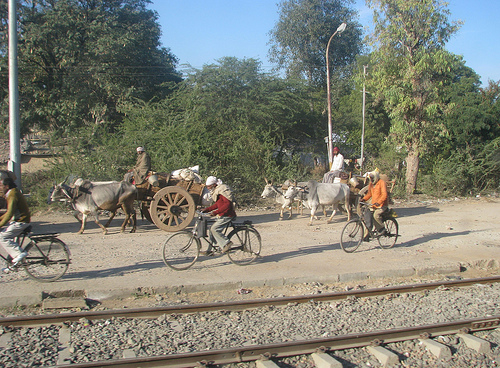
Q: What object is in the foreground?
A: Train tracks.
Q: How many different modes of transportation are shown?
A: Two.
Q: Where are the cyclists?
A: Between the train tracks and the wagons.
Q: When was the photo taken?
A: During the day.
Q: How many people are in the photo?
A: Five.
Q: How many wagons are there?
A: Two.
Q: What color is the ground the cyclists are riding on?
A: Brown.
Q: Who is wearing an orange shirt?
A: The cyclist on the right.